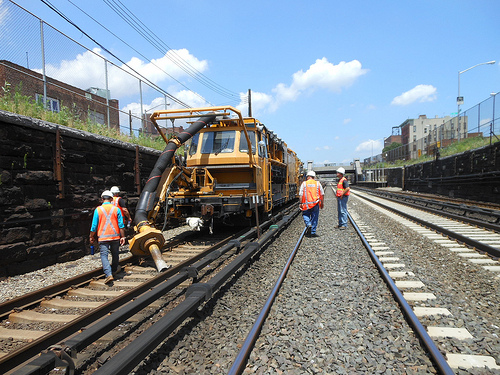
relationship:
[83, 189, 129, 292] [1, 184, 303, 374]
workers on tracks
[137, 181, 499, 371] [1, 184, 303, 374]
gravel between tracks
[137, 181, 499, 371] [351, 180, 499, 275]
gravel between tracks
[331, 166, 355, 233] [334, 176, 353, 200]
workers wearing vest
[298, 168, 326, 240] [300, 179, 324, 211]
workers wearing vest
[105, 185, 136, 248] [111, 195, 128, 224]
workers wearing vest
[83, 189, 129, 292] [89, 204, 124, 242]
workers wearing shirt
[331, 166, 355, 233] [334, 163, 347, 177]
workers wearing hats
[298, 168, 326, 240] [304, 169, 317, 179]
workers wearing hats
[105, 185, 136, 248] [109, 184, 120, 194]
workers wearing hats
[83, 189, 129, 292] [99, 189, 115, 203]
workers wearing hats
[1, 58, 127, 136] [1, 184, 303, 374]
building above tracks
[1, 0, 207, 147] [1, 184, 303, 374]
fence above tracks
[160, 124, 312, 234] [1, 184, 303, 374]
train on tracks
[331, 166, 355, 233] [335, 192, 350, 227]
workers wearing jeans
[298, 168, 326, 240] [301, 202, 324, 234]
workers wearing jeans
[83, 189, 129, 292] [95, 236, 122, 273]
workers wearing jeans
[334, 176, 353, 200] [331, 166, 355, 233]
vest on workers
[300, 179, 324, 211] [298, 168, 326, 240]
vest on workers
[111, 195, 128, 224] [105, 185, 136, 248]
vest on workers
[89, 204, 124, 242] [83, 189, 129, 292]
shirt on workers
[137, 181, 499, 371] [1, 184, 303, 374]
gravel along tracks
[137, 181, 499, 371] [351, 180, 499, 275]
gravel along tracks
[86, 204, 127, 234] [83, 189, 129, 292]
shirt on workers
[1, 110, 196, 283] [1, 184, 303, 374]
wall next to tracks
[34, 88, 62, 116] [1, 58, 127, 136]
window in building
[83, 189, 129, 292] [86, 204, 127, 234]
workers wearing shirt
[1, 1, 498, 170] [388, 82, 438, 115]
sky with clouds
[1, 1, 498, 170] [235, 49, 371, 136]
sky with clouds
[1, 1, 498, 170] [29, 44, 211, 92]
sky with clouds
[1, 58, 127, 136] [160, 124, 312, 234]
building above train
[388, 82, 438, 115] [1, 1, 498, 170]
clouds in sky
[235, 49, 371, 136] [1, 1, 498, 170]
clouds in sky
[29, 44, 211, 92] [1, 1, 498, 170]
clouds in sky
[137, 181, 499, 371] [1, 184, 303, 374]
gravel on tracks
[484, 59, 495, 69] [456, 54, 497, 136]
light on pole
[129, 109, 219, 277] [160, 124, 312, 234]
hose on train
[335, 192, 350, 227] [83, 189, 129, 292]
jeans on workers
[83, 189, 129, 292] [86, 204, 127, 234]
workers in shirt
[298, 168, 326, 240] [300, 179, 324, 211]
workers in vest